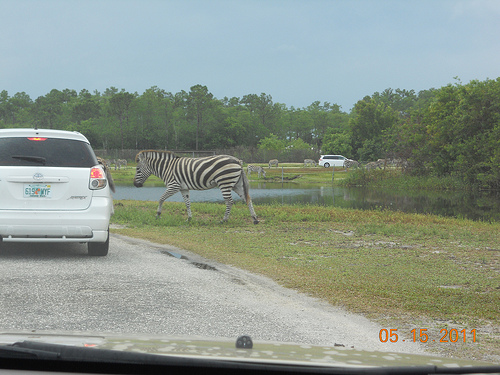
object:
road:
[0, 235, 413, 370]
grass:
[107, 199, 497, 327]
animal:
[304, 159, 317, 168]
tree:
[396, 75, 500, 215]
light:
[28, 137, 47, 141]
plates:
[21, 180, 51, 198]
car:
[0, 127, 113, 256]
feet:
[154, 208, 192, 223]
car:
[318, 155, 354, 169]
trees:
[3, 73, 355, 158]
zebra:
[133, 150, 259, 226]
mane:
[136, 148, 182, 157]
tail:
[241, 170, 249, 205]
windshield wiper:
[13, 151, 48, 164]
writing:
[69, 196, 87, 201]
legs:
[220, 184, 257, 218]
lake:
[109, 182, 498, 221]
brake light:
[90, 167, 103, 179]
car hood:
[0, 333, 497, 375]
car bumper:
[0, 227, 111, 244]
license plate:
[23, 184, 51, 198]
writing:
[24, 184, 51, 197]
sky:
[1, 0, 500, 93]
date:
[376, 327, 477, 345]